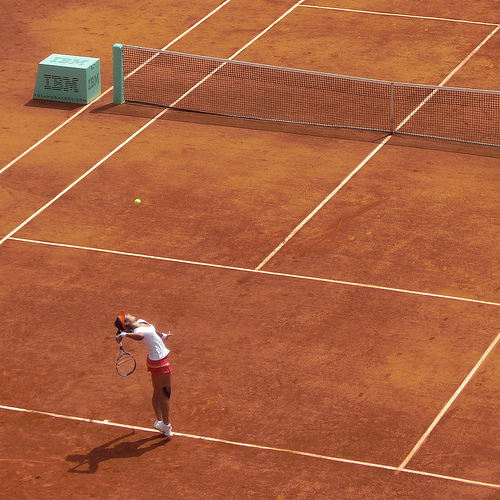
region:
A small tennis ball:
[126, 196, 148, 212]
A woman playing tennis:
[112, 309, 185, 452]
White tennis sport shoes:
[147, 414, 177, 435]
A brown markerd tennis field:
[213, 401, 347, 499]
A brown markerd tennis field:
[347, 420, 461, 496]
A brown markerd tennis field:
[387, 268, 495, 351]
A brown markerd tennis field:
[227, 226, 364, 317]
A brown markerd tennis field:
[12, 386, 99, 478]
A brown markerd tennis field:
[9, 209, 76, 291]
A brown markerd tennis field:
[6, 147, 102, 202]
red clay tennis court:
[1, 0, 496, 497]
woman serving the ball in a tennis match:
[116, 195, 176, 438]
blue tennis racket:
[114, 343, 136, 375]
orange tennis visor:
[117, 307, 124, 330]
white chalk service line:
[1, 400, 488, 493]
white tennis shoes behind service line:
[154, 419, 174, 438]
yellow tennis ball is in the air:
[131, 196, 142, 206]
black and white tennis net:
[124, 38, 497, 153]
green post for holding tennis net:
[111, 43, 123, 108]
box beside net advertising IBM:
[31, 52, 102, 101]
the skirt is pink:
[153, 360, 167, 372]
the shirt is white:
[144, 330, 165, 360]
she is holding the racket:
[108, 330, 137, 364]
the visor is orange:
[112, 307, 128, 329]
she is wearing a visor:
[113, 308, 132, 330]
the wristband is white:
[119, 329, 130, 340]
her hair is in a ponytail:
[112, 320, 124, 337]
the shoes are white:
[154, 415, 176, 445]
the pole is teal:
[106, 41, 128, 78]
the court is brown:
[316, 348, 358, 408]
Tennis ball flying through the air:
[116, 182, 153, 218]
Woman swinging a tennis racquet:
[107, 310, 176, 380]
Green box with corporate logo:
[33, 48, 102, 111]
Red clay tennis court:
[0, 0, 495, 498]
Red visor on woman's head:
[106, 307, 134, 334]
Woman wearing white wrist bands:
[111, 313, 173, 353]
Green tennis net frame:
[110, 43, 127, 108]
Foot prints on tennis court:
[340, 285, 499, 409]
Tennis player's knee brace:
[150, 381, 179, 406]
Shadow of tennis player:
[45, 432, 176, 483]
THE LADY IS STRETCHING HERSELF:
[74, 283, 243, 481]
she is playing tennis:
[41, 267, 225, 474]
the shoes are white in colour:
[141, 401, 198, 458]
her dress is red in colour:
[141, 345, 183, 389]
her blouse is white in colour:
[123, 323, 190, 360]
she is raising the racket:
[95, 296, 240, 438]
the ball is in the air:
[130, 188, 148, 213]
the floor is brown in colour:
[131, 168, 368, 403]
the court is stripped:
[146, 218, 333, 348]